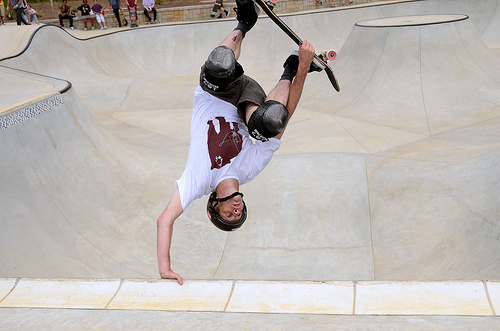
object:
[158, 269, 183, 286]
hand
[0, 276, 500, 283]
curb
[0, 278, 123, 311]
concrete tile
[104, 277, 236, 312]
concrete tile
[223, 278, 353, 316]
concrete tile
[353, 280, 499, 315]
concrete tile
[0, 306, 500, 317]
edge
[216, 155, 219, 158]
muzzle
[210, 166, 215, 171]
ear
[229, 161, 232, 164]
ear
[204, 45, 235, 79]
kneepad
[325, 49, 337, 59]
wheel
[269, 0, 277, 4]
wheel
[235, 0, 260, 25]
sneaker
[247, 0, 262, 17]
rubber sole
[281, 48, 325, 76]
sneaker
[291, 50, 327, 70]
rubber sole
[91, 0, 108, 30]
person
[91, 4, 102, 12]
shirt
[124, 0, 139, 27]
person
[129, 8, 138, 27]
skateboard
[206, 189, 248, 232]
helmet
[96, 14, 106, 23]
pants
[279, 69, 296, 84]
sock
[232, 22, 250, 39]
sock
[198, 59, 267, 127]
pants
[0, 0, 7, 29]
people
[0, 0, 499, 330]
background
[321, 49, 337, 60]
wheels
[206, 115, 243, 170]
bear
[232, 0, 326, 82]
black shoes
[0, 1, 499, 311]
skate trail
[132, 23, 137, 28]
skater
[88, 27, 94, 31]
skater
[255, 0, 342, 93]
skateboard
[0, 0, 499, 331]
outdoor scene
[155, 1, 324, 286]
boy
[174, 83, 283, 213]
shirt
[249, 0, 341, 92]
board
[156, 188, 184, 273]
arm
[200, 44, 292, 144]
kneepads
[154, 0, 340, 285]
skateboarder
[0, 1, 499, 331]
skate park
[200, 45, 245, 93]
pad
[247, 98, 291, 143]
pad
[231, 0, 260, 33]
shoe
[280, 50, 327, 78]
shoe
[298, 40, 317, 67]
hand